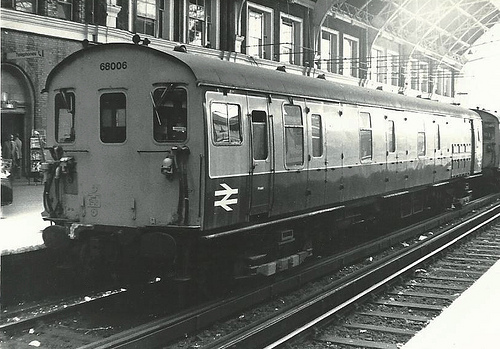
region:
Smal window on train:
[204, 88, 246, 171]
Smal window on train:
[146, 78, 190, 159]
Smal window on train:
[85, 80, 140, 156]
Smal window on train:
[46, 85, 86, 163]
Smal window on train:
[247, 104, 270, 171]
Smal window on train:
[272, 98, 308, 181]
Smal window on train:
[305, 110, 325, 173]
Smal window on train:
[351, 103, 374, 195]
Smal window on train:
[380, 110, 393, 165]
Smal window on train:
[409, 110, 431, 160]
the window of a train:
[92, 85, 133, 146]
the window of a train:
[44, 82, 84, 145]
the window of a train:
[148, 81, 193, 145]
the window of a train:
[203, 98, 243, 148]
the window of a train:
[357, 106, 377, 166]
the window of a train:
[280, 100, 305, 168]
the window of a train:
[412, 128, 425, 155]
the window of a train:
[245, 107, 271, 163]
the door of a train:
[246, 90, 274, 212]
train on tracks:
[39, 28, 499, 282]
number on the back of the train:
[92, 59, 136, 71]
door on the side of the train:
[242, 109, 272, 217]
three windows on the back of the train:
[58, 88, 190, 146]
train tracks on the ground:
[0, 181, 497, 348]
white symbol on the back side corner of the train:
[208, 176, 240, 217]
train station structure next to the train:
[0, 4, 497, 184]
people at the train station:
[5, 128, 25, 183]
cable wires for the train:
[1, 38, 487, 93]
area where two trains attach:
[469, 108, 499, 178]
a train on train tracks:
[23, 34, 498, 282]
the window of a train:
[308, 108, 327, 160]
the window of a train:
[381, 111, 399, 156]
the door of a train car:
[88, 80, 148, 234]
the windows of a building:
[319, 20, 365, 79]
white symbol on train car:
[210, 177, 244, 217]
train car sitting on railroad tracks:
[38, 28, 483, 299]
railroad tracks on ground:
[3, 169, 495, 347]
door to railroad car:
[245, 100, 279, 219]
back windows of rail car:
[48, 83, 197, 157]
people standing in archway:
[3, 128, 25, 180]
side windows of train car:
[210, 88, 428, 170]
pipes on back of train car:
[33, 140, 202, 229]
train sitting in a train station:
[5, 2, 496, 344]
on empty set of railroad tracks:
[203, 153, 498, 347]